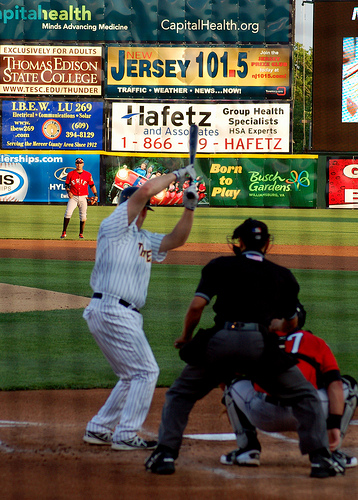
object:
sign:
[99, 152, 319, 206]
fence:
[0, 1, 356, 208]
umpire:
[142, 216, 347, 478]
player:
[219, 320, 354, 469]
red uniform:
[253, 327, 338, 396]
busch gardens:
[248, 168, 291, 194]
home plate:
[185, 430, 236, 444]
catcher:
[298, 314, 357, 444]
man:
[142, 220, 331, 478]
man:
[218, 307, 357, 467]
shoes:
[109, 435, 158, 449]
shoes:
[81, 427, 113, 444]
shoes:
[333, 451, 357, 466]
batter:
[81, 160, 198, 450]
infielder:
[61, 159, 88, 239]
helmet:
[232, 220, 266, 255]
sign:
[106, 40, 299, 102]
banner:
[107, 44, 291, 101]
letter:
[109, 47, 125, 83]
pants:
[74, 297, 191, 440]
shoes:
[304, 456, 346, 479]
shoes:
[220, 446, 266, 467]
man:
[61, 160, 92, 243]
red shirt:
[65, 172, 93, 197]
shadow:
[165, 215, 358, 222]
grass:
[1, 203, 356, 390]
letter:
[177, 56, 192, 81]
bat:
[187, 124, 198, 199]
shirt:
[94, 207, 152, 303]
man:
[90, 161, 202, 447]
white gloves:
[182, 181, 198, 210]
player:
[64, 251, 203, 470]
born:
[56, 465, 120, 500]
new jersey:
[60, 255, 109, 328]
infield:
[17, 250, 356, 401]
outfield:
[6, 188, 356, 260]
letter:
[125, 56, 138, 85]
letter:
[176, 53, 196, 84]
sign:
[103, 90, 305, 162]